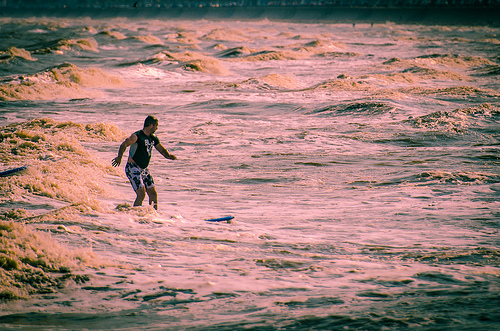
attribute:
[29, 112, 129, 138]
waves — turbulent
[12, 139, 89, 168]
waves — turbulent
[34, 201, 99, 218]
waves — turbulent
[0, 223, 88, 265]
waves — turbulent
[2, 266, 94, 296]
waves — turbulent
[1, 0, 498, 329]
waves — choppy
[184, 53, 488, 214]
ocean — dirty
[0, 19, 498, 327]
water — shiny, coral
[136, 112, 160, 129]
hair — black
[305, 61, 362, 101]
wave — small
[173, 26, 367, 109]
waves — choppy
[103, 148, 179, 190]
shorts — black, white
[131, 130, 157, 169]
tank — black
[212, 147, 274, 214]
reflection — pink